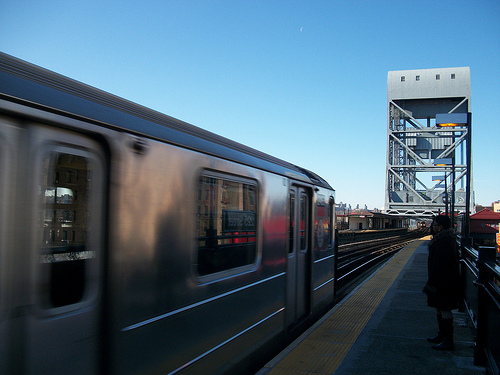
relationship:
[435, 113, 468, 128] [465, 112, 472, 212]
light on post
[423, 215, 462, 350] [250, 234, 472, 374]
woman on platform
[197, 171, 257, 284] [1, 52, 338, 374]
window on train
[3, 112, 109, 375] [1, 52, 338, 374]
door on train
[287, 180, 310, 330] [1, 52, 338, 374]
door on train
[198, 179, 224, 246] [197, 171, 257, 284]
building in window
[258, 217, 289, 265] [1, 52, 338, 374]
reflection on train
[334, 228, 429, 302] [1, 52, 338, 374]
railroad behind train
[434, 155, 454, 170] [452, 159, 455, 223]
light on post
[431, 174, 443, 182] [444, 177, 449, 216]
light on post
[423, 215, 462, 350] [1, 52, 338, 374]
person beside train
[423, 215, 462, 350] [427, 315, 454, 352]
woman wearing boots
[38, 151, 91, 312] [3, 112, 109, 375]
window on door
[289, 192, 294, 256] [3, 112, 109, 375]
window on door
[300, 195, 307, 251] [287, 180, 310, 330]
window on door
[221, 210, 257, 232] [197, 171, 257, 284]
sign in window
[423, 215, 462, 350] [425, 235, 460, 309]
woman wearing a coat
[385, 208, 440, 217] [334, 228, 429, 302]
overpass over railroad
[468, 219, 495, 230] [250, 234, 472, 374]
roof by platform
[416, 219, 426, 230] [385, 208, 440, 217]
train under overpass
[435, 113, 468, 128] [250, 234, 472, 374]
light over platform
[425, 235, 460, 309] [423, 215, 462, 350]
coat on woman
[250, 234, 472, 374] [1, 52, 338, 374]
platform for train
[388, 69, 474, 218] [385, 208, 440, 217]
stucture over overpass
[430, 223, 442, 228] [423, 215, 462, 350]
glasses on woman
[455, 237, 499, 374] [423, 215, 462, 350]
rail behind woman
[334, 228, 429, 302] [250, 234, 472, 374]
railroad alongside platform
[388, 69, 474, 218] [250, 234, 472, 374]
stucture over platform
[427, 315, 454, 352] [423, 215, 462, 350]
boots on woman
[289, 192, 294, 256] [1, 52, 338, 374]
window on side of train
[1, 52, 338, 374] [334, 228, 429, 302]
train on railroad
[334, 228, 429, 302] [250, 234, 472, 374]
railroad beside platform